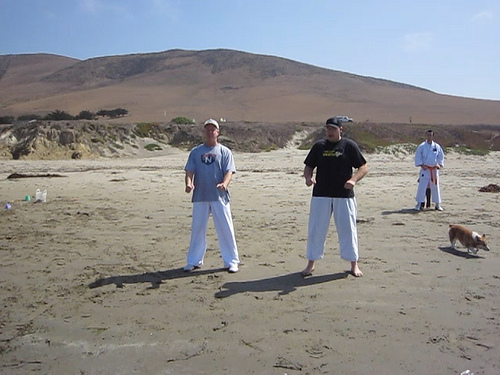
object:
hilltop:
[5, 48, 392, 89]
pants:
[295, 189, 372, 290]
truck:
[327, 115, 352, 125]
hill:
[0, 47, 498, 129]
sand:
[0, 47, 500, 375]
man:
[301, 116, 369, 277]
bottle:
[36, 188, 42, 202]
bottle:
[42, 189, 47, 203]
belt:
[417, 163, 441, 183]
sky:
[0, 0, 499, 100]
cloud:
[403, 29, 494, 83]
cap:
[323, 117, 342, 128]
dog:
[446, 223, 492, 256]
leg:
[449, 235, 456, 247]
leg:
[468, 243, 475, 251]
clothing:
[415, 139, 445, 208]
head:
[325, 125, 340, 141]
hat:
[203, 120, 221, 129]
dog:
[441, 214, 496, 269]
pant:
[175, 194, 255, 263]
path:
[283, 121, 309, 150]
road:
[0, 159, 496, 175]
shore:
[4, 117, 500, 157]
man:
[415, 128, 445, 211]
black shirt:
[303, 138, 368, 198]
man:
[183, 119, 240, 273]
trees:
[0, 106, 127, 124]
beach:
[0, 142, 500, 375]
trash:
[24, 195, 30, 202]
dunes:
[28, 121, 169, 160]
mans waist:
[417, 162, 439, 175]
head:
[205, 124, 218, 139]